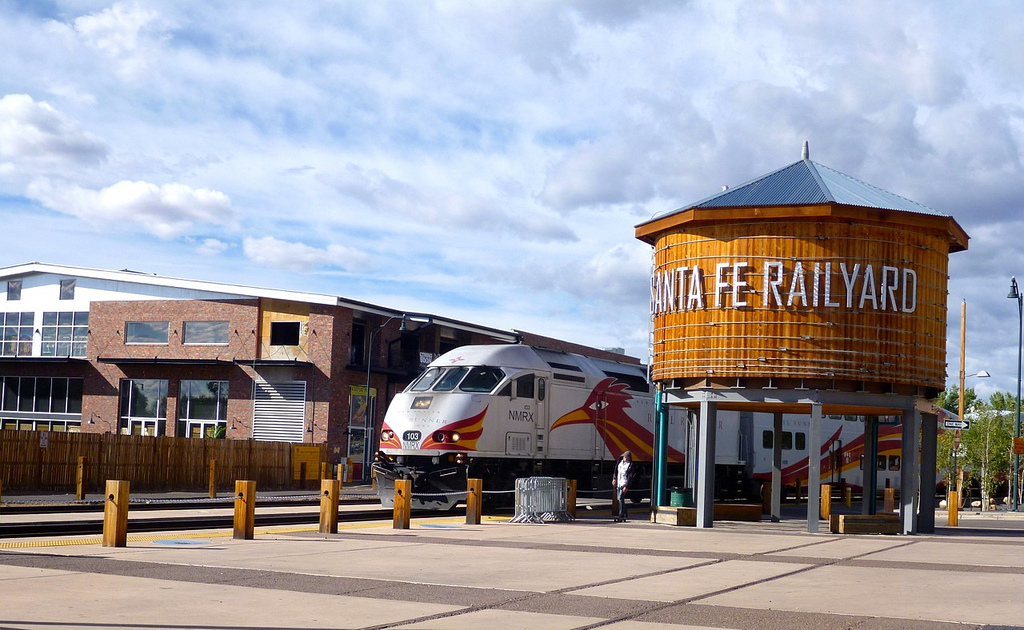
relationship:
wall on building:
[307, 301, 396, 433] [147, 253, 342, 392]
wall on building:
[307, 301, 400, 473] [307, 312, 377, 472]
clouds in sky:
[0, 3, 1016, 384] [407, 195, 554, 280]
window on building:
[0, 310, 88, 357] [39, 256, 221, 408]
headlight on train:
[428, 415, 491, 454] [405, 327, 622, 466]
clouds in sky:
[1, 13, 1023, 376] [5, 3, 1021, 366]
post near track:
[105, 476, 132, 548] [1, 487, 468, 526]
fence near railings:
[10, 432, 361, 487] [5, 448, 328, 481]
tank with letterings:
[641, 154, 970, 377] [653, 255, 934, 320]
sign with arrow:
[934, 411, 987, 433] [932, 409, 972, 442]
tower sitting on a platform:
[641, 152, 964, 531] [21, 512, 1022, 627]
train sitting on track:
[379, 337, 889, 500] [1, 476, 524, 533]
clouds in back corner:
[0, 3, 1016, 384] [822, 3, 1023, 220]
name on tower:
[660, 264, 928, 321] [641, 152, 964, 531]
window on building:
[116, 316, 166, 343] [88, 288, 400, 476]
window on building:
[184, 320, 230, 343] [88, 288, 400, 476]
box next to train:
[518, 472, 585, 522] [379, 337, 889, 500]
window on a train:
[407, 361, 496, 383] [379, 337, 889, 500]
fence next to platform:
[0, 430, 336, 493] [5, 495, 1015, 623]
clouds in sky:
[0, 3, 1016, 384] [5, 3, 1021, 366]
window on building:
[172, 316, 235, 343] [77, 286, 436, 447]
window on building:
[79, 303, 419, 442] [116, 316, 171, 338]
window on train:
[406, 361, 502, 393] [303, 279, 742, 491]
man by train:
[604, 430, 659, 497] [401, 312, 842, 535]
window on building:
[23, 309, 106, 368] [3, 230, 356, 492]